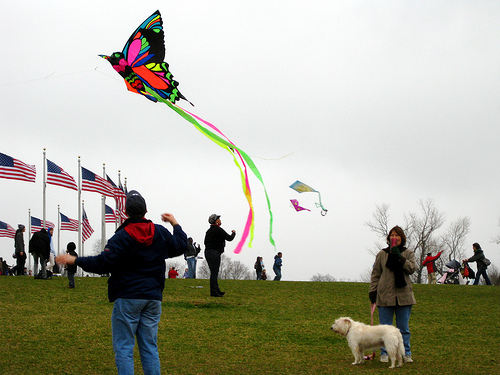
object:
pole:
[76, 153, 83, 277]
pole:
[99, 162, 107, 251]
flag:
[0, 152, 39, 184]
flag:
[45, 157, 78, 192]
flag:
[58, 211, 80, 231]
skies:
[94, 9, 279, 254]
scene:
[0, 0, 499, 375]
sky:
[0, 0, 499, 283]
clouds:
[0, 0, 499, 285]